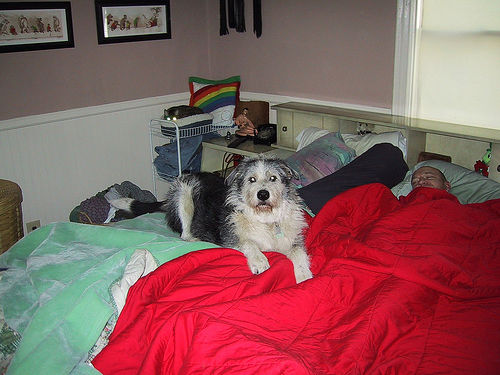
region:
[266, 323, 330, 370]
The blanket is red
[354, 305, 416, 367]
The blanket is red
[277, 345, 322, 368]
The blanket is red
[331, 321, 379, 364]
The blanket is red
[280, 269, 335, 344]
The blanket is red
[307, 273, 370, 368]
The blanket is red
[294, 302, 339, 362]
The blanket is red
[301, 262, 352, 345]
The blanket is red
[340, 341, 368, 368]
The blanket is red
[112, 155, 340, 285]
Dog sleeping on the bed.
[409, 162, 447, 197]
Head of guy laying on the bed.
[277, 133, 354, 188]
Multiple colored pillow on bed.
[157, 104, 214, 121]
Cat laying on top of rack.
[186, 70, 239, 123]
Rainbow colored pillow on rack.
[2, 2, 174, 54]
Two pillows hanging on wall.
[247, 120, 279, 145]
Black telephone on nightstand.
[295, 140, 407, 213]
Black pillow on bed.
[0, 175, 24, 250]
Wooden clothing hamper.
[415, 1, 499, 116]
White window shade.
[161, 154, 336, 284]
white and black dog on a bed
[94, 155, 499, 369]
red blanket over a sleeping man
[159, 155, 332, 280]
dog on a bed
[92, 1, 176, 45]
art hanging on a wall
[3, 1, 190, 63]
two pieces of art with a brown frame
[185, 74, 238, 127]
pillow with a rainbow design on it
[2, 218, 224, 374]
light green blanket on a bed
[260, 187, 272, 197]
dog's nose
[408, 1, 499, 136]
window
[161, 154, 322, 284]
dog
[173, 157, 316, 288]
Beautiful dog laying on top of a red blanket.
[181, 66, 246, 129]
Rainbow pillow on top of wire baskets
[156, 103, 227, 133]
Cat laying on a wire basket.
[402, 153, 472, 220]
Man's head laying in his bed.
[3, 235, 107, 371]
Green fuzzy blanket on bed.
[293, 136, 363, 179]
Multicolored pillow on bed.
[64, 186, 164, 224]
Pile of clothes on the floor.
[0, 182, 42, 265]
Wicker laundry basket.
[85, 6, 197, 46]
Picture on the wall.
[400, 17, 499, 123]
Shade on the window.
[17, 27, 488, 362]
A bedroom scene is pictured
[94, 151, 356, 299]
A dog is lying on the bed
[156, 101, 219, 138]
A cat is shown here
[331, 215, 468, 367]
The blanket is red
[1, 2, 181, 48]
Framed paintings are on the wall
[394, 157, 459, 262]
A man is under the blanket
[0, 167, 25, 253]
This is a clothes hamper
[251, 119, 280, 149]
A telephone is on the nightstand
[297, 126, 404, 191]
These are pillows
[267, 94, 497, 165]
This is the bed's headboard